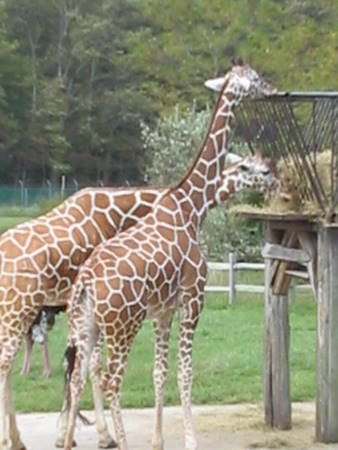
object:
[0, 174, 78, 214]
fence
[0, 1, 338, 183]
forest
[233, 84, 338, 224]
basket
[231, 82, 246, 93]
spots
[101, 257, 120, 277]
spots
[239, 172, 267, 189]
spots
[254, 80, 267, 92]
spots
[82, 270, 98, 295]
spots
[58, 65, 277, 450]
animal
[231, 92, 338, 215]
feeding mechanism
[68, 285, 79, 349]
tail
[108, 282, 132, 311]
spots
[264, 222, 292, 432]
beam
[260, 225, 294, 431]
pillar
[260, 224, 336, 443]
wood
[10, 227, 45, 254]
brown spot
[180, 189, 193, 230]
spots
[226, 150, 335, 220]
hay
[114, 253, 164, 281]
spots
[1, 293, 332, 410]
grass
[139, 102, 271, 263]
tree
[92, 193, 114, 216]
spots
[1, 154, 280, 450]
animal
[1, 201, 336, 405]
field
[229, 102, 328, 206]
bars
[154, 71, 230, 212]
brown mane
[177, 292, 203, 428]
leg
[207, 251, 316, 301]
fence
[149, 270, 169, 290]
spot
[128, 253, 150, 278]
spot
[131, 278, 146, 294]
spot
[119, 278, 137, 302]
spot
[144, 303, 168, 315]
spot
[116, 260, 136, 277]
spot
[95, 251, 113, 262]
spot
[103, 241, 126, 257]
spot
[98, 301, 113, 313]
spot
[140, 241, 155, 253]
spot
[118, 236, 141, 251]
spot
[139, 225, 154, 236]
spot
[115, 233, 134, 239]
spot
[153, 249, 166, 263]
spot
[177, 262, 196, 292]
spot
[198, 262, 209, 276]
spot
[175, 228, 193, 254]
spot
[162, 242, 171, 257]
spot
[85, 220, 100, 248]
spot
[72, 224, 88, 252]
spot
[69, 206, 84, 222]
spot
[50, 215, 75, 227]
spot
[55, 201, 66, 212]
spot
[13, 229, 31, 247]
spot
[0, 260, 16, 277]
spot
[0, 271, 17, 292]
spot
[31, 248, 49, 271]
spot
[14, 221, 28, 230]
spot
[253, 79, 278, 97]
ear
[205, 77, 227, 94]
ear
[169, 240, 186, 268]
spot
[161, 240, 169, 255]
spot